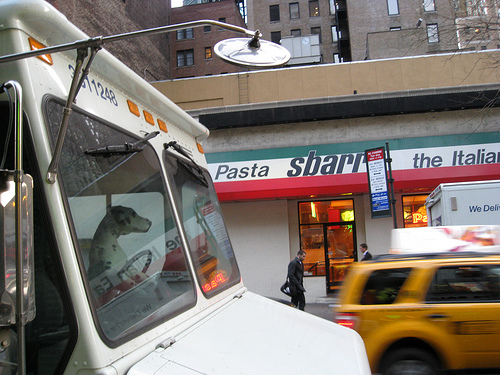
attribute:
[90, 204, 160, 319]
dog — black, white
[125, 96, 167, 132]
reflectors — yellow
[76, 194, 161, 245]
dog — dalmatian, observing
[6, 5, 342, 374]
truck — white, parked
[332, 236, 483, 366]
cab — yellow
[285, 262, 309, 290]
coat — brown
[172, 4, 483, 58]
buildings — brown